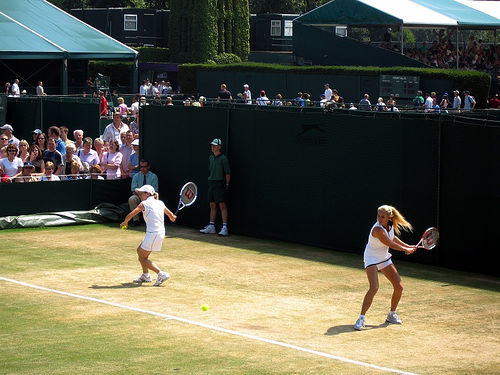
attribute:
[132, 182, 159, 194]
hat — white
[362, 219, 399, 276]
cotton dress — white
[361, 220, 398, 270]
tennis dress — white, cotton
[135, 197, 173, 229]
shirt — white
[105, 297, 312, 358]
line — white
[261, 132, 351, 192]
fence — green, tarp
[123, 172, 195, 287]
woman — playing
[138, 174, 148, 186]
tie — around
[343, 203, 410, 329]
woman — playing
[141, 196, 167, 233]
shirt — white, cotton, sleeveless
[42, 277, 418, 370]
line — white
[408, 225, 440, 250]
racket — red, white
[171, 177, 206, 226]
tennis racquet — blue, metal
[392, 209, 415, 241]
hair — brown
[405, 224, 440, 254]
tennis racquet — red, white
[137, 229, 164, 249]
skirt — cotton, white, tennis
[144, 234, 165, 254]
shorts — white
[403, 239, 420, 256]
hand — woman's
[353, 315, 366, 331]
shoes — white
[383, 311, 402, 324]
shoes — white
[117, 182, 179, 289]
woman — playing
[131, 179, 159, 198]
cap — white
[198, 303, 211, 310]
tennis ball — yellow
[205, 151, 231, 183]
polo shirt — cotton, green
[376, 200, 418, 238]
hair — long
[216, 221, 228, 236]
sneaker — white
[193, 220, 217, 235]
sneaker — white